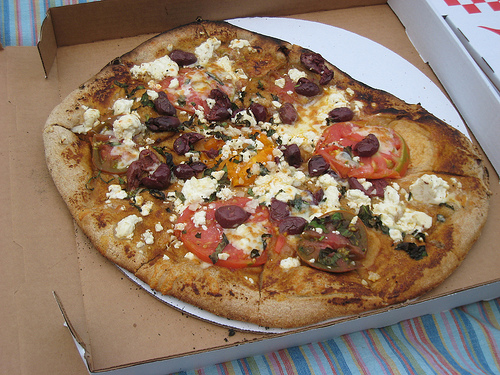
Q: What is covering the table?
A: A table cloth.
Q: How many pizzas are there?
A: One.